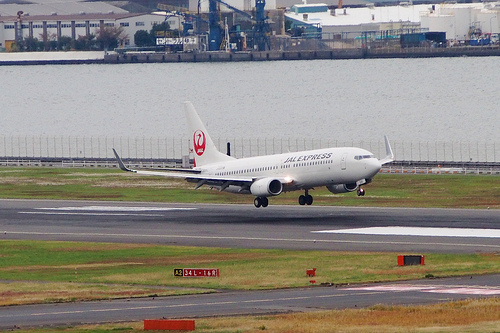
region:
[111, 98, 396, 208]
white red and black jet taking off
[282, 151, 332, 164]
black lettering on right side of jet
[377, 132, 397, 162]
left wing of jet taking off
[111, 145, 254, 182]
right wing of jet taking off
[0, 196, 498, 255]
black top runway beneath jet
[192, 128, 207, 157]
red and white symbol on left side of tail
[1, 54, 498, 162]
tall white wall behind runway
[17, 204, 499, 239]
white painted markings on black runway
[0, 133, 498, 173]
short metal fence in front of white wall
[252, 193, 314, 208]
right and left wheels of jet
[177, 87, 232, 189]
the tail of a plane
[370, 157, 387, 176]
the nose of a plane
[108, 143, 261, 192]
the wing of a plane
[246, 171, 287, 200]
the engine of a plane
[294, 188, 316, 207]
the wheels of a plane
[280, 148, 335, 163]
writing on the plane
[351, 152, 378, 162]
the windshield of a plane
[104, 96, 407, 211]
a plane in the air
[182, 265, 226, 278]
a small red sign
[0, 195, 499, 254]
a gray paved tarmac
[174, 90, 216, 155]
Tail of white airplane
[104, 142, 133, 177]
WingTip of white airplane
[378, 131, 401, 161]
Wing tip of white airplane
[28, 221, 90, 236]
Part of airplane runway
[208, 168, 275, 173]
Passenger windows of white airplane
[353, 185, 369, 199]
Front wheel of white airplane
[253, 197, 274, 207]
Back wheels of white airplane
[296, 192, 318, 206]
Back wheels of white airplane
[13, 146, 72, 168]
Pairt of airport fence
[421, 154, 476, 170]
Part of airport fence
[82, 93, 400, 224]
airplane on the runway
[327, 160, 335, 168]
window on side of the plane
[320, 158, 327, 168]
window on side of the plane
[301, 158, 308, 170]
window on side of the plane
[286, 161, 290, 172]
window on side of the plane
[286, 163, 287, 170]
window on side of the plane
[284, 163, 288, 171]
window on side of the plane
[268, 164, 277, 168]
window on side of the plane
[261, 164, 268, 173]
window on side of the plane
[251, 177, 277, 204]
engine on side of the plane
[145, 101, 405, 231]
white airplane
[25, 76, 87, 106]
gray water in the river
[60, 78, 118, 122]
gray water in the river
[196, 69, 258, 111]
gray water in the river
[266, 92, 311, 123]
gray water in the river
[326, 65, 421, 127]
gray water in the river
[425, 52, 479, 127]
gray water in the river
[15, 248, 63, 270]
short green and brown grass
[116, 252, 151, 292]
short green and brown grass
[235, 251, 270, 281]
short green and brown grass